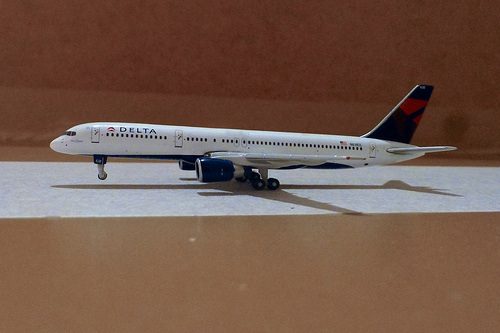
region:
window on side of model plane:
[105, 132, 113, 142]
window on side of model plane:
[119, 130, 124, 142]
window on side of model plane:
[144, 130, 150, 137]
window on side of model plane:
[183, 133, 187, 143]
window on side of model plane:
[200, 135, 209, 149]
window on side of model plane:
[220, 135, 224, 145]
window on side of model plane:
[208, 135, 222, 145]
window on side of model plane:
[254, 137, 264, 150]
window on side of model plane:
[301, 137, 308, 153]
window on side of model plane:
[281, 138, 290, 146]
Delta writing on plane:
[117, 121, 158, 138]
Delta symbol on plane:
[102, 123, 117, 137]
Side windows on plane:
[102, 129, 365, 159]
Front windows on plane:
[62, 126, 78, 139]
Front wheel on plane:
[87, 150, 113, 184]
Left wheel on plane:
[250, 166, 285, 193]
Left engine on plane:
[192, 155, 239, 187]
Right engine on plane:
[175, 149, 198, 174]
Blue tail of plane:
[358, 79, 435, 145]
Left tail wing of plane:
[385, 137, 463, 162]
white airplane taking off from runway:
[50, 81, 453, 196]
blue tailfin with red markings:
[368, 82, 438, 139]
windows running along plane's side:
[97, 126, 369, 155]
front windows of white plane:
[59, 127, 78, 139]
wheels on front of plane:
[90, 160, 111, 182]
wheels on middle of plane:
[234, 166, 284, 192]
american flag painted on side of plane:
[335, 138, 354, 146]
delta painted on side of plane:
[120, 125, 164, 136]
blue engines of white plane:
[173, 150, 238, 184]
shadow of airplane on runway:
[51, 153, 441, 220]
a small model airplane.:
[34, 69, 452, 196]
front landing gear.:
[81, 135, 111, 180]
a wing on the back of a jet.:
[354, 53, 443, 142]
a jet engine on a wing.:
[191, 150, 232, 185]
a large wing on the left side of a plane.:
[169, 128, 467, 168]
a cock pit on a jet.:
[46, 114, 95, 171]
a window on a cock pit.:
[59, 113, 84, 138]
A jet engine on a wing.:
[176, 140, 274, 198]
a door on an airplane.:
[169, 120, 190, 159]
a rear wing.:
[373, 132, 469, 167]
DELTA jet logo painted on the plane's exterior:
[106, 119, 160, 138]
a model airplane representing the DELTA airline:
[51, 89, 451, 191]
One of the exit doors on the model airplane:
[169, 122, 188, 151]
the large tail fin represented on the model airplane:
[377, 75, 430, 145]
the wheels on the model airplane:
[246, 167, 282, 198]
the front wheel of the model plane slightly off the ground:
[85, 151, 115, 183]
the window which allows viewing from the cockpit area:
[44, 120, 81, 156]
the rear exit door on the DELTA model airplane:
[365, 138, 380, 168]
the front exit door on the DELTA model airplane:
[89, 121, 102, 149]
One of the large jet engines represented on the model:
[190, 148, 237, 187]